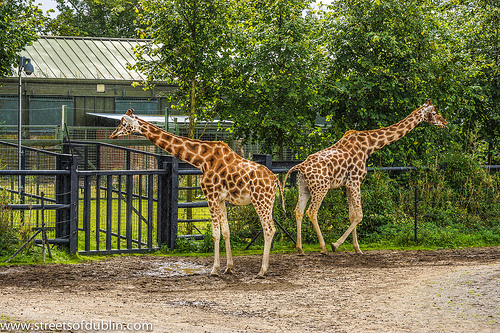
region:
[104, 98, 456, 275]
these are two giraffes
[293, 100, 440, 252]
the giraffe is walking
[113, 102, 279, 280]
the giraffe is standing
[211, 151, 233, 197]
the fur is brown in color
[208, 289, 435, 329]
this is the ground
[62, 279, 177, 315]
the sand is brown in color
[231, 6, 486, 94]
these are two trees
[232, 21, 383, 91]
the leaves are green in color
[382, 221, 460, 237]
this is the grass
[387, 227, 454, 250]
lthe grass is green in color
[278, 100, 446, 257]
a tall giraffe standing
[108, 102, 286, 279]
a tall giraffe standing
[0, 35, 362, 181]
a building in the background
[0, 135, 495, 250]
a wooden fence enclosure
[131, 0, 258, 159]
a green tree in the picture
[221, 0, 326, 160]
a green tree in the picture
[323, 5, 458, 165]
a green tree in the picture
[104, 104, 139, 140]
the head of a giraffe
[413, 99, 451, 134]
the head of a giraffe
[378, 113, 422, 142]
the neck of a giraffe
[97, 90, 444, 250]
the giraffes are opposite each other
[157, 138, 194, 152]
the giraffe has long neck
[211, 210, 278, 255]
the legs are long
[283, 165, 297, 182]
the tail is thin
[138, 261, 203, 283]
mud is on the ground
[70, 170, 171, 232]
the gate is closed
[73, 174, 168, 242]
the gate is metallic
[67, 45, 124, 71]
this is the roof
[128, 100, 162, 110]
the window is closed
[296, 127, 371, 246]
this is a giraffe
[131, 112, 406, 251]
the giraffes are two in number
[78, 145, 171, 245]
this is a gate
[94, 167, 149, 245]
the gate is made of metal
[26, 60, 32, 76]
this is a lump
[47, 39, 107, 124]
this is a house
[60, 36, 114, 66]
this is the roof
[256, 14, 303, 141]
this is a tree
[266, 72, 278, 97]
the tree has green leaves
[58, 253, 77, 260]
this is a grass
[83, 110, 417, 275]
Giraffes on muddy ground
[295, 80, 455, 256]
Giraffe walking on muddy ground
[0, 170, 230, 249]
Grey fence of metal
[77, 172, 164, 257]
Grey colored metal gate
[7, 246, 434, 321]
Ground covered with mud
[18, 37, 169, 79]
Building with tinned roof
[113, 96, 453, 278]
Giraffes with brown spots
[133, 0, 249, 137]
Tree with green leaves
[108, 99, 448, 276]
Giraffes facing opposite directions